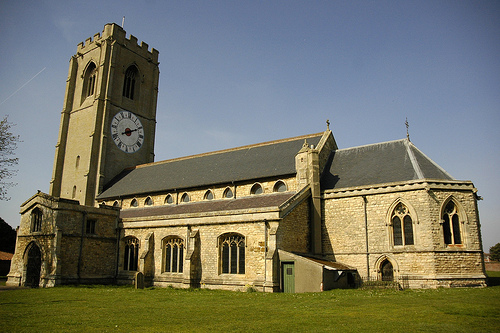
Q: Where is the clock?
A: On the tower.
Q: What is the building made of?
A: Stone.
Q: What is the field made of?
A: Grass.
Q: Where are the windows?
A: On the building.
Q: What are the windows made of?
A: Glass.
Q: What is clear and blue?
A: The sky.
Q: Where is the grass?
A: On the ground.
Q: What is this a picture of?
A: A building.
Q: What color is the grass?
A: Green.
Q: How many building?
A: One.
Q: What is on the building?
A: A clock.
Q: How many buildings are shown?
A: One.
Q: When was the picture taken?
A: Daytime.